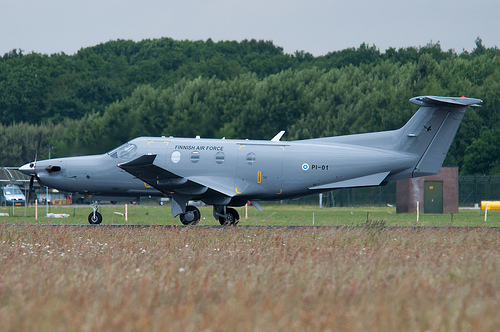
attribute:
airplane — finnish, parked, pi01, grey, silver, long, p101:
[6, 116, 439, 234]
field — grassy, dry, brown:
[129, 255, 247, 312]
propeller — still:
[13, 153, 54, 171]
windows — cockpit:
[168, 143, 261, 175]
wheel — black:
[174, 204, 209, 234]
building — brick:
[2, 177, 20, 183]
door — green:
[36, 192, 51, 204]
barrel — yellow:
[478, 197, 498, 208]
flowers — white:
[31, 204, 60, 220]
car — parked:
[33, 190, 53, 203]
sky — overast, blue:
[122, 0, 162, 12]